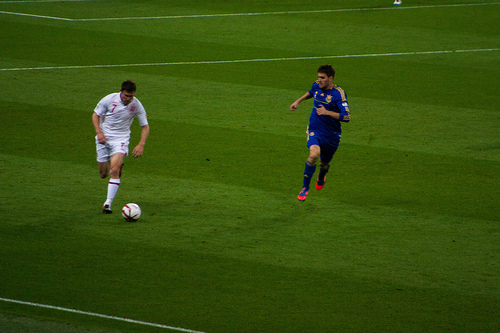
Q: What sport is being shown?
A: Soccer.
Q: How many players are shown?
A: 2.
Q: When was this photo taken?
A: Daytime.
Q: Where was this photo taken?
A: Soccer field.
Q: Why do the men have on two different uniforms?
A: Opposing teams.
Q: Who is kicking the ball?
A: Man in white.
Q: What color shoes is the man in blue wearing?
A: Red.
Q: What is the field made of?
A: Turf.